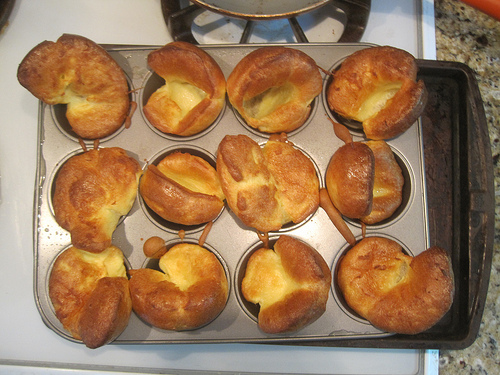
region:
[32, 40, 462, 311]
Popovers in a pan.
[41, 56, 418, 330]
The pan is silver.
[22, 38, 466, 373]
The pan is on another pan.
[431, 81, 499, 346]
The bottom pan is black.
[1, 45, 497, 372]
The pans are on an oven.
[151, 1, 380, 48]
A burner next to the pans.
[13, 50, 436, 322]
The popovers are brown.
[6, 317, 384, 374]
The oven is white.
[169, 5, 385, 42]
The burner is black.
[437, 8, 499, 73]
The counter is granite.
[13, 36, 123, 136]
dark brown colored bread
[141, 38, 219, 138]
dark brown colored bread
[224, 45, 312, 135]
dark brown colored bread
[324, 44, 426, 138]
dark brown colored bread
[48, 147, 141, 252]
dark brown colored bread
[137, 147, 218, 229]
dark brown colored bread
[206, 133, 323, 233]
dark brown colored bread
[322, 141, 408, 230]
dark brown colored bread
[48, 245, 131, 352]
dark brown colored bread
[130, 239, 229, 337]
dark brown colored bread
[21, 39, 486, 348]
Croissants in a backing dish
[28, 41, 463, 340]
Twelve croissants in a backing dish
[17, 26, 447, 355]
Croissants in a silver backing dish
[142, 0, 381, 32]
part of a stove top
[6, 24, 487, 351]
Croissants in a cupcake dish sitting inside a baking dish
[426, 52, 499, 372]
part of a baking dish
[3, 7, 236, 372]
croissants on a white stove top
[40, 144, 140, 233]
One croissant in a cupcake baking dish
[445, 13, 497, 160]
Part of a kitchen counter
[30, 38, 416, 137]
Four golden brown croissants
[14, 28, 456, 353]
Popovers in a muffin tin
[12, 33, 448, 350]
baked goods in a muffin pan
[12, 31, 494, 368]
a pan on top of a pan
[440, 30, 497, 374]
granit countertop under the pan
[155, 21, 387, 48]
a burner on a stove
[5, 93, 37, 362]
a white stove top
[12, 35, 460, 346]
twelve popovers in a pan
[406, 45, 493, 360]
a sheet pan under a muffin pan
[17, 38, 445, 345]
a non-stick muffin tin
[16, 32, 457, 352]
golden popovers in a muffin pan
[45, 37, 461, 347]
a pan of rolls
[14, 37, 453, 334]
a pan of fresh baked bread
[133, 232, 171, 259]
a large brown crumb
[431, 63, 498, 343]
a black metal pan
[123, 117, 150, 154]
a silver muffin pan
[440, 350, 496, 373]
black and gray granite countertop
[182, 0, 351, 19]
a pan on the stove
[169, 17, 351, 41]
a black iron burner rack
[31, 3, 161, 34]
the top of a white stover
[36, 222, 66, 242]
small droplets of oil